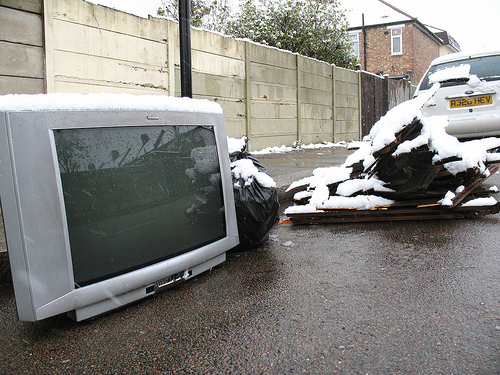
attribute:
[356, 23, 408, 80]
wall — brown, brick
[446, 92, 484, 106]
plate — rectangular yellow license 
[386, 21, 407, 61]
house — window 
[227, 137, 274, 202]
snow — black plastic bags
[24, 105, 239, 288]
reflections — TV screen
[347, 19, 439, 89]
bricks — house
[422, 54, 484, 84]
wiper —  black windshield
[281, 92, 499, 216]
boxes — cardboard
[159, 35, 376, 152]
fence — white, wooden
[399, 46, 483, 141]
car — white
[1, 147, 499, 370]
ground — wet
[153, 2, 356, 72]
leaves — green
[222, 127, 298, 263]
trash bag — black, plastic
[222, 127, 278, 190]
snow — white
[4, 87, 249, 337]
television screen — silver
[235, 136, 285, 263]
bag — black, plastic